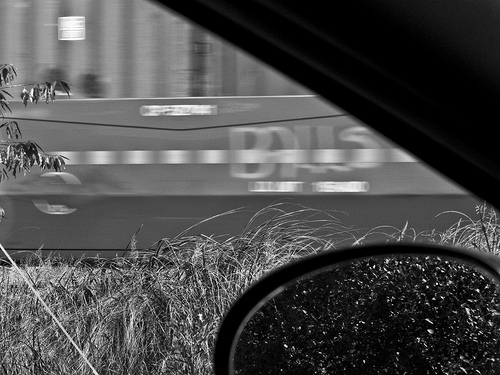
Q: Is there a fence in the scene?
A: No, there are no fences.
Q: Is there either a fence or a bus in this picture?
A: No, there are no fences or buses.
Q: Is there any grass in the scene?
A: Yes, there is grass.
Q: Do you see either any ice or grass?
A: Yes, there is grass.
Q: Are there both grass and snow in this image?
A: No, there is grass but no snow.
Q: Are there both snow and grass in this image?
A: No, there is grass but no snow.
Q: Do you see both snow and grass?
A: No, there is grass but no snow.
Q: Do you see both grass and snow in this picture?
A: No, there is grass but no snow.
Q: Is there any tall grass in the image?
A: Yes, there is tall grass.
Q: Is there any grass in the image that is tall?
A: Yes, there is grass that is tall.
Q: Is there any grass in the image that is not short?
A: Yes, there is tall grass.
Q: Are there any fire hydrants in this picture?
A: No, there are no fire hydrants.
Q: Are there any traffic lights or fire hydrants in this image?
A: No, there are no fire hydrants or traffic lights.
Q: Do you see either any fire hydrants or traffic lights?
A: No, there are no fire hydrants or traffic lights.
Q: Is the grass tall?
A: Yes, the grass is tall.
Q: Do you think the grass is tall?
A: Yes, the grass is tall.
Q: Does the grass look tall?
A: Yes, the grass is tall.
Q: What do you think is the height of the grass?
A: The grass is tall.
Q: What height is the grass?
A: The grass is tall.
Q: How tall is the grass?
A: The grass is tall.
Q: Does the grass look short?
A: No, the grass is tall.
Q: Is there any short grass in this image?
A: No, there is grass but it is tall.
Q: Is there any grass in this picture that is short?
A: No, there is grass but it is tall.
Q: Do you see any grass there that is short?
A: No, there is grass but it is tall.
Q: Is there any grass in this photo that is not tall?
A: No, there is grass but it is tall.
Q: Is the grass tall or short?
A: The grass is tall.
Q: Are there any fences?
A: No, there are no fences.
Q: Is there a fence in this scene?
A: No, there are no fences.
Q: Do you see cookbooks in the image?
A: No, there are no cookbooks.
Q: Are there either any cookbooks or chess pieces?
A: No, there are no cookbooks or chess pieces.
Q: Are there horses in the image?
A: Yes, there is a horse.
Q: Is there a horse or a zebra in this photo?
A: Yes, there is a horse.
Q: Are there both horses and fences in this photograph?
A: No, there is a horse but no fences.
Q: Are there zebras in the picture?
A: No, there are no zebras.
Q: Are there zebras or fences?
A: No, there are no zebras or fences.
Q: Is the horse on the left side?
A: Yes, the horse is on the left of the image.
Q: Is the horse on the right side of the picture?
A: No, the horse is on the left of the image.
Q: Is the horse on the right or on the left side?
A: The horse is on the left of the image.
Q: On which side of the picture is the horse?
A: The horse is on the left of the image.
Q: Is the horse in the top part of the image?
A: Yes, the horse is in the top of the image.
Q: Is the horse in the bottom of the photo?
A: No, the horse is in the top of the image.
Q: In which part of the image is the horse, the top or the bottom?
A: The horse is in the top of the image.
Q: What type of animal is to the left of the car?
A: The animal is a horse.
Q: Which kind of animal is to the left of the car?
A: The animal is a horse.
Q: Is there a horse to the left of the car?
A: Yes, there is a horse to the left of the car.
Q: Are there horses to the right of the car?
A: No, the horse is to the left of the car.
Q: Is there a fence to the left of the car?
A: No, there is a horse to the left of the car.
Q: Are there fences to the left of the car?
A: No, there is a horse to the left of the car.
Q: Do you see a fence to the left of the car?
A: No, there is a horse to the left of the car.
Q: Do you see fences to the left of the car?
A: No, there is a horse to the left of the car.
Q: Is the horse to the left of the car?
A: Yes, the horse is to the left of the car.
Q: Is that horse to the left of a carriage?
A: No, the horse is to the left of the car.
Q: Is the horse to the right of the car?
A: No, the horse is to the left of the car.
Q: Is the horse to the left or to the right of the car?
A: The horse is to the left of the car.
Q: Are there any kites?
A: No, there are no kites.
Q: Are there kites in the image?
A: No, there are no kites.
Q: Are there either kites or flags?
A: No, there are no kites or flags.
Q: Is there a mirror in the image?
A: Yes, there is a mirror.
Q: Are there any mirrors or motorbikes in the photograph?
A: Yes, there is a mirror.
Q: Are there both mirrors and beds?
A: No, there is a mirror but no beds.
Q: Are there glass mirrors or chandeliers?
A: Yes, there is a glass mirror.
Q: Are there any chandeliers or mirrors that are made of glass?
A: Yes, the mirror is made of glass.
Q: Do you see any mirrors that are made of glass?
A: Yes, there is a mirror that is made of glass.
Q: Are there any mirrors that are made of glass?
A: Yes, there is a mirror that is made of glass.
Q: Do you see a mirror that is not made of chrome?
A: Yes, there is a mirror that is made of glass.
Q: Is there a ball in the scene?
A: No, there are no balls.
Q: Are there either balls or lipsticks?
A: No, there are no balls or lipsticks.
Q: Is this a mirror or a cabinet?
A: This is a mirror.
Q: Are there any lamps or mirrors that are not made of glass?
A: No, there is a mirror but it is made of glass.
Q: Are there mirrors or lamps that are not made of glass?
A: No, there is a mirror but it is made of glass.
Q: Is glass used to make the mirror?
A: Yes, the mirror is made of glass.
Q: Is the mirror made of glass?
A: Yes, the mirror is made of glass.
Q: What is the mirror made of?
A: The mirror is made of glass.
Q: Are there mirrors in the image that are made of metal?
A: No, there is a mirror but it is made of glass.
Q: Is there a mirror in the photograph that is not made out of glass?
A: No, there is a mirror but it is made of glass.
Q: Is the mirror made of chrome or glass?
A: The mirror is made of glass.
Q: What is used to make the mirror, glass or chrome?
A: The mirror is made of glass.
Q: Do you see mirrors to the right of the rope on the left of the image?
A: Yes, there is a mirror to the right of the rope.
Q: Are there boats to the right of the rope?
A: No, there is a mirror to the right of the rope.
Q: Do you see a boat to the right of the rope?
A: No, there is a mirror to the right of the rope.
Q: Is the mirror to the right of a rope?
A: Yes, the mirror is to the right of a rope.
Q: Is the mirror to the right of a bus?
A: No, the mirror is to the right of a rope.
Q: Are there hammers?
A: No, there are no hammers.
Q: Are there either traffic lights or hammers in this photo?
A: No, there are no hammers or traffic lights.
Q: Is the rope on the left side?
A: Yes, the rope is on the left of the image.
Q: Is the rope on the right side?
A: No, the rope is on the left of the image.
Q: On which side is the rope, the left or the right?
A: The rope is on the left of the image.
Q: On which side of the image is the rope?
A: The rope is on the left of the image.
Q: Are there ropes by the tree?
A: Yes, there is a rope by the tree.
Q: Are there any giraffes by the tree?
A: No, there is a rope by the tree.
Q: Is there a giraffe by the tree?
A: No, there is a rope by the tree.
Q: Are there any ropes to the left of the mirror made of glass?
A: Yes, there is a rope to the left of the mirror.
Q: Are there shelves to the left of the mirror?
A: No, there is a rope to the left of the mirror.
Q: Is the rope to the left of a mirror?
A: Yes, the rope is to the left of a mirror.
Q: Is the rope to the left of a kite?
A: No, the rope is to the left of a mirror.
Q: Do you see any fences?
A: No, there are no fences.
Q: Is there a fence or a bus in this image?
A: No, there are no fences or buses.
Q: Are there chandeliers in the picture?
A: No, there are no chandeliers.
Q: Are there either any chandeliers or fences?
A: No, there are no chandeliers or fences.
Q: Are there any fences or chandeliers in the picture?
A: No, there are no chandeliers or fences.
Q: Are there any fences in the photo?
A: No, there are no fences.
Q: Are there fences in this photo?
A: No, there are no fences.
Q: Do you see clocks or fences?
A: No, there are no fences or clocks.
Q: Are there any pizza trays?
A: No, there are no pizza trays.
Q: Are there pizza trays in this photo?
A: No, there are no pizza trays.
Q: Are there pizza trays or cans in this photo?
A: No, there are no pizza trays or cans.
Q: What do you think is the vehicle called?
A: The vehicle is a car.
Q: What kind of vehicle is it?
A: The vehicle is a car.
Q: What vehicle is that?
A: This is a car.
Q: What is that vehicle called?
A: This is a car.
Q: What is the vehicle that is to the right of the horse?
A: The vehicle is a car.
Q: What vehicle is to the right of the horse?
A: The vehicle is a car.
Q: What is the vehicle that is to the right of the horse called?
A: The vehicle is a car.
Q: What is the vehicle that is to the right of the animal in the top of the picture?
A: The vehicle is a car.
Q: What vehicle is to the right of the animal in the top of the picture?
A: The vehicle is a car.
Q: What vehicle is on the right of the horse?
A: The vehicle is a car.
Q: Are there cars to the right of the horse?
A: Yes, there is a car to the right of the horse.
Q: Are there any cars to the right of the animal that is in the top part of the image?
A: Yes, there is a car to the right of the horse.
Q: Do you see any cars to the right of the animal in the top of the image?
A: Yes, there is a car to the right of the horse.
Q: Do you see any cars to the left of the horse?
A: No, the car is to the right of the horse.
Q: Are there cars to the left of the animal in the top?
A: No, the car is to the right of the horse.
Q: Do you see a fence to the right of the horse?
A: No, there is a car to the right of the horse.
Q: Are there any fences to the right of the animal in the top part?
A: No, there is a car to the right of the horse.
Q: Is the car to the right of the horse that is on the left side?
A: Yes, the car is to the right of the horse.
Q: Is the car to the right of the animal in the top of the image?
A: Yes, the car is to the right of the horse.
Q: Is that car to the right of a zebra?
A: No, the car is to the right of the horse.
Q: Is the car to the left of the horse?
A: No, the car is to the right of the horse.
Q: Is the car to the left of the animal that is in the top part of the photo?
A: No, the car is to the right of the horse.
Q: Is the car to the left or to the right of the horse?
A: The car is to the right of the horse.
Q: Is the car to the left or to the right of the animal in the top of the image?
A: The car is to the right of the horse.